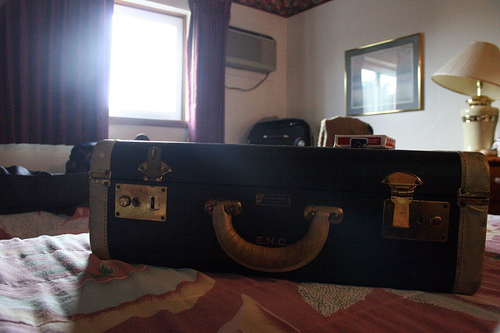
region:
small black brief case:
[60, 128, 494, 288]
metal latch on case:
[389, 190, 419, 227]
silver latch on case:
[380, 171, 420, 233]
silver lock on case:
[373, 171, 456, 246]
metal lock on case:
[365, 175, 445, 249]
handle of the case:
[196, 202, 341, 269]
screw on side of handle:
[329, 208, 346, 223]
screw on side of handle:
[300, 208, 317, 221]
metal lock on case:
[93, 182, 175, 224]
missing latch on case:
[138, 143, 174, 181]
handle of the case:
[225, 210, 307, 252]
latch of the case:
[122, 183, 174, 229]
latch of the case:
[384, 187, 435, 224]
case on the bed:
[60, 140, 486, 293]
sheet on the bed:
[162, 284, 265, 322]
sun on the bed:
[17, 267, 62, 288]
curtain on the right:
[212, 36, 227, 133]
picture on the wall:
[337, 30, 421, 118]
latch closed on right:
[386, 198, 413, 235]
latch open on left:
[137, 144, 170, 181]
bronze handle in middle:
[193, 202, 340, 275]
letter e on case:
[249, 231, 267, 251]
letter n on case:
[262, 232, 277, 249]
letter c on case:
[275, 229, 290, 251]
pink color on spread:
[208, 297, 224, 317]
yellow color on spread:
[161, 295, 185, 307]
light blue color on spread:
[96, 288, 116, 303]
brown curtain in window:
[37, 58, 60, 89]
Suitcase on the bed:
[87, 136, 485, 291]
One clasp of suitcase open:
[110, 146, 165, 221]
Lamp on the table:
[430, 35, 495, 151]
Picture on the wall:
[340, 30, 420, 115]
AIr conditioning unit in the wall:
[220, 20, 275, 75]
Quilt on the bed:
[0, 235, 497, 325]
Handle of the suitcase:
[200, 190, 341, 277]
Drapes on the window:
[0, 0, 230, 155]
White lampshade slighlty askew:
[432, 38, 498, 92]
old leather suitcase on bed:
[84, 134, 491, 299]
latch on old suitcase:
[384, 168, 425, 233]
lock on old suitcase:
[113, 180, 175, 223]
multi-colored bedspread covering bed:
[1, 199, 499, 331]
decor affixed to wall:
[334, 32, 429, 119]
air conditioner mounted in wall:
[218, 23, 282, 78]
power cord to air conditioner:
[221, 69, 273, 94]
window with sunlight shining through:
[111, 3, 189, 129]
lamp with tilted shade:
[431, 37, 498, 155]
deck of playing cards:
[332, 132, 402, 155]